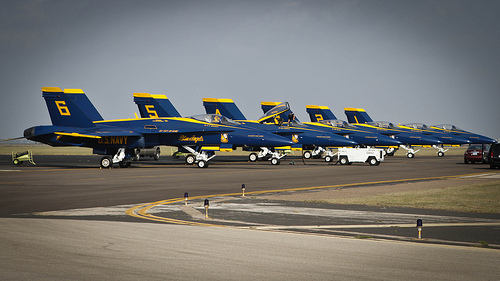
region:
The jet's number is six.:
[51, 97, 73, 119]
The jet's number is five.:
[142, 102, 161, 119]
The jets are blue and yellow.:
[3, 85, 498, 168]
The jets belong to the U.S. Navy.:
[93, 135, 132, 147]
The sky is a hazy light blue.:
[0, 0, 499, 137]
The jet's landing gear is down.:
[97, 143, 456, 169]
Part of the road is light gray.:
[1, 217, 499, 279]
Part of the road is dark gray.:
[1, 155, 487, 216]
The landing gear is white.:
[100, 145, 454, 170]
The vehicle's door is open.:
[479, 139, 498, 169]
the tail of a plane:
[2, 82, 103, 152]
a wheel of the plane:
[98, 151, 115, 172]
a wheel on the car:
[365, 155, 380, 170]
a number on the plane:
[50, 94, 73, 122]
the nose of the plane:
[271, 128, 299, 155]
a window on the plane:
[188, 106, 242, 131]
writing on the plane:
[91, 130, 133, 147]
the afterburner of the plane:
[21, 124, 40, 144]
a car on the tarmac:
[458, 133, 495, 168]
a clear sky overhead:
[0, 0, 499, 146]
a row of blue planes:
[34, 77, 493, 159]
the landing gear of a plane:
[98, 149, 129, 169]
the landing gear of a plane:
[185, 147, 216, 168]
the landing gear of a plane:
[249, 147, 289, 165]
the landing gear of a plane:
[424, 142, 449, 157]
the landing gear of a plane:
[403, 145, 421, 158]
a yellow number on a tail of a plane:
[51, 92, 73, 118]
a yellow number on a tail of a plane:
[143, 100, 160, 121]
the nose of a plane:
[188, 117, 249, 139]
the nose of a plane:
[243, 123, 300, 153]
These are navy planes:
[25, 98, 283, 260]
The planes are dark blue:
[88, 117, 287, 227]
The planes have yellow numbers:
[30, 95, 148, 146]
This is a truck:
[338, 135, 442, 202]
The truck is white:
[323, 122, 419, 227]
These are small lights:
[125, 161, 290, 278]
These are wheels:
[93, 150, 155, 163]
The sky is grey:
[138, 21, 385, 228]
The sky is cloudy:
[110, 2, 221, 64]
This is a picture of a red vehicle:
[461, 128, 477, 158]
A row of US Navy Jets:
[24, 84, 494, 162]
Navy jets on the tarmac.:
[23, 80, 498, 166]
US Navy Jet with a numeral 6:
[50, 95, 77, 119]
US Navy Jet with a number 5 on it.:
[143, 105, 160, 122]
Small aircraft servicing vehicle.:
[336, 140, 382, 163]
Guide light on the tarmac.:
[198, 198, 210, 219]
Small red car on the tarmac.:
[466, 144, 486, 169]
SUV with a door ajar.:
[483, 138, 498, 173]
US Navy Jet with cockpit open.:
[256, 103, 298, 133]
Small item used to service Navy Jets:
[10, 148, 36, 167]